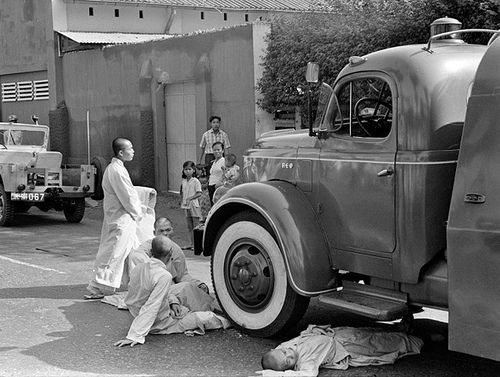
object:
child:
[178, 160, 204, 252]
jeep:
[0, 112, 101, 229]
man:
[252, 318, 451, 377]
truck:
[193, 12, 500, 365]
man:
[112, 234, 234, 348]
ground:
[1, 189, 497, 377]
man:
[127, 215, 209, 298]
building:
[0, 0, 367, 203]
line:
[0, 252, 68, 274]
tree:
[253, 0, 498, 130]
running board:
[315, 289, 407, 321]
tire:
[207, 208, 311, 341]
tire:
[61, 194, 87, 226]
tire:
[0, 186, 15, 226]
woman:
[206, 140, 229, 207]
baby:
[218, 153, 240, 190]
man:
[80, 135, 160, 302]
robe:
[86, 156, 156, 296]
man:
[197, 114, 234, 180]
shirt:
[199, 128, 234, 156]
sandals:
[82, 291, 104, 300]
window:
[351, 77, 396, 138]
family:
[172, 141, 244, 254]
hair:
[207, 115, 222, 123]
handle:
[376, 166, 394, 180]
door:
[318, 65, 403, 257]